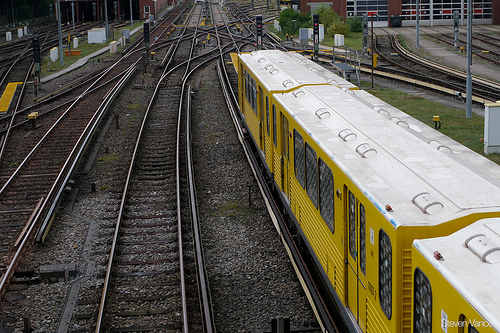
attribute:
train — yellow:
[234, 44, 495, 331]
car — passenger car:
[235, 45, 499, 315]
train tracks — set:
[4, 3, 243, 322]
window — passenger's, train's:
[320, 160, 340, 229]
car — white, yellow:
[237, 35, 343, 157]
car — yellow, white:
[267, 84, 498, 329]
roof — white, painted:
[235, 46, 498, 326]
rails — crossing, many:
[7, 8, 494, 325]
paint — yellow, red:
[1, 81, 23, 109]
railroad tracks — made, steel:
[7, 4, 425, 315]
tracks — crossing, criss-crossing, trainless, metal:
[4, 20, 363, 332]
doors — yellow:
[345, 187, 368, 319]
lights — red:
[256, 16, 264, 34]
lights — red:
[312, 14, 322, 34]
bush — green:
[323, 22, 352, 36]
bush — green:
[276, 7, 305, 34]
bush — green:
[342, 11, 367, 30]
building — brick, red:
[294, 0, 499, 32]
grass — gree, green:
[317, 35, 367, 52]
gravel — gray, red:
[9, 5, 226, 317]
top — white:
[239, 45, 495, 324]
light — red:
[254, 22, 262, 28]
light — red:
[313, 22, 317, 27]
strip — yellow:
[3, 81, 23, 108]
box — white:
[483, 104, 500, 155]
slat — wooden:
[297, 52, 499, 108]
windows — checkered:
[345, 188, 373, 270]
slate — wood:
[283, 47, 499, 101]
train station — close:
[292, 0, 500, 37]